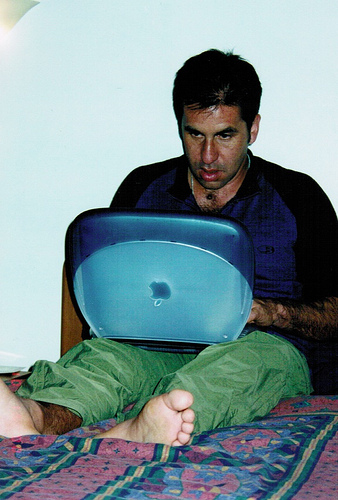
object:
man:
[0, 48, 337, 446]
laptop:
[65, 209, 255, 353]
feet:
[0, 375, 195, 447]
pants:
[14, 329, 314, 439]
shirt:
[82, 148, 338, 367]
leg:
[41, 325, 239, 437]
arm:
[273, 298, 337, 340]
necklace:
[191, 148, 252, 195]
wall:
[0, 0, 337, 447]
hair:
[172, 48, 262, 142]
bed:
[0, 262, 338, 500]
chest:
[193, 194, 229, 216]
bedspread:
[0, 371, 337, 500]